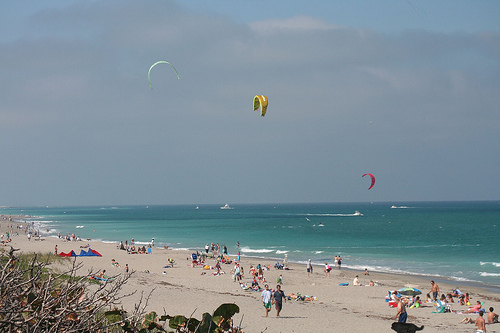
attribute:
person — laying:
[462, 315, 477, 323]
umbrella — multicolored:
[391, 285, 423, 302]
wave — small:
[302, 209, 353, 218]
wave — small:
[476, 261, 497, 269]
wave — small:
[476, 271, 493, 281]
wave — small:
[242, 246, 291, 253]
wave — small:
[76, 223, 86, 229]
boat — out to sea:
[222, 201, 235, 211]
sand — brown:
[0, 212, 499, 329]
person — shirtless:
[395, 300, 410, 326]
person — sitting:
[354, 275, 364, 287]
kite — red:
[361, 171, 376, 189]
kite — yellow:
[255, 94, 268, 116]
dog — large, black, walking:
[389, 321, 422, 331]